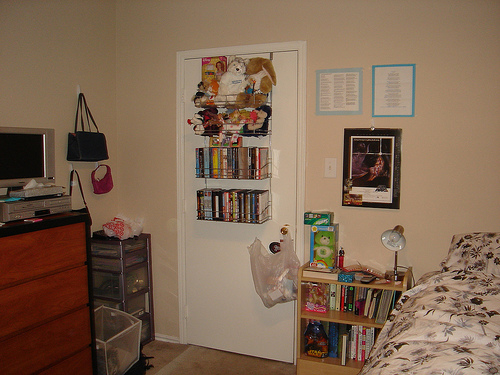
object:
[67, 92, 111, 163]
purse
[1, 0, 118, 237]
wall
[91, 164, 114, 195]
purse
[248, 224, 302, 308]
bag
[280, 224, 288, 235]
door handle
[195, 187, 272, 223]
book shelves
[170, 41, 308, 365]
door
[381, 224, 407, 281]
lamp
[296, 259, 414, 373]
book shelf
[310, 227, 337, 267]
teddy bear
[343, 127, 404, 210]
poster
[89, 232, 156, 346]
storage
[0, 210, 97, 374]
dresser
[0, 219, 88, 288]
drawer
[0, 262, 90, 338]
drawer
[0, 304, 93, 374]
drawer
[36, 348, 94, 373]
drawer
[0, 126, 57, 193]
computer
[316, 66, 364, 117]
paper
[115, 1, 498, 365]
wall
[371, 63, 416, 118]
paper